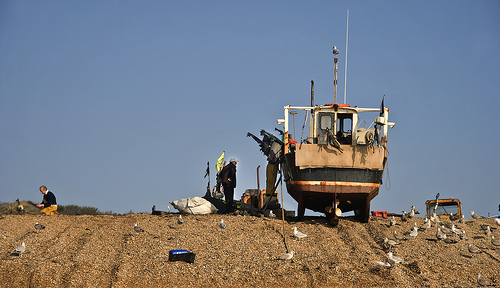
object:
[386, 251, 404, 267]
bird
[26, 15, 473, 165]
clouds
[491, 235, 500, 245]
bird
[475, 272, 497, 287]
bird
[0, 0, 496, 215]
blue sky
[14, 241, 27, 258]
bird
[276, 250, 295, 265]
bird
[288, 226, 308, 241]
bird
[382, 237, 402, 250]
bird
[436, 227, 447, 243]
bird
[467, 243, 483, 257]
bird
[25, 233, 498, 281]
sand